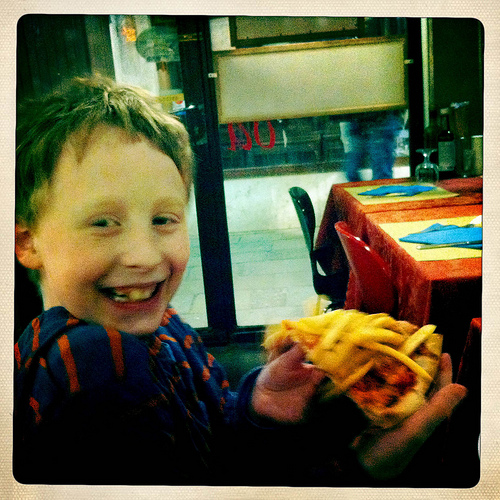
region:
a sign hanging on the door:
[212, 38, 409, 117]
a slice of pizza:
[262, 307, 442, 422]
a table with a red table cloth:
[336, 180, 486, 326]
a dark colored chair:
[286, 186, 344, 307]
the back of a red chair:
[336, 222, 403, 309]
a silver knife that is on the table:
[415, 240, 486, 250]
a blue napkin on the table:
[405, 220, 482, 251]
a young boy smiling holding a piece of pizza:
[18, 112, 465, 487]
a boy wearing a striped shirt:
[16, 111, 246, 466]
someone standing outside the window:
[339, 116, 404, 178]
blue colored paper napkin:
[403, 230, 478, 248]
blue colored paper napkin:
[362, 182, 439, 201]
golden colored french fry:
[365, 340, 433, 381]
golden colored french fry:
[403, 323, 435, 353]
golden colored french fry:
[324, 357, 375, 396]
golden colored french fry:
[323, 312, 355, 352]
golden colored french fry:
[333, 324, 403, 369]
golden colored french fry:
[281, 319, 318, 338]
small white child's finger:
[420, 381, 468, 423]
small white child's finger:
[439, 351, 456, 390]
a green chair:
[284, 185, 349, 308]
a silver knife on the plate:
[418, 238, 480, 245]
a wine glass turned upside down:
[413, 145, 440, 185]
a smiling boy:
[13, 74, 193, 475]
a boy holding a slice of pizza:
[18, 85, 467, 488]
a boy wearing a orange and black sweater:
[16, 80, 263, 491]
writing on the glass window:
[220, 123, 280, 153]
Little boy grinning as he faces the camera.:
[21, 70, 208, 342]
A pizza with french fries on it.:
[242, 289, 458, 434]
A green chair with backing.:
[277, 176, 358, 324]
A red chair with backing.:
[327, 218, 410, 328]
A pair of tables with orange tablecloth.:
[325, 169, 482, 331]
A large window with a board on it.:
[227, 19, 409, 353]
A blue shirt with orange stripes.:
[27, 305, 287, 497]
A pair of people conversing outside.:
[328, 83, 420, 196]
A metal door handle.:
[180, 95, 215, 152]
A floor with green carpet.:
[187, 330, 324, 385]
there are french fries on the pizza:
[248, 287, 450, 442]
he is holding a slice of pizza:
[16, 15, 496, 497]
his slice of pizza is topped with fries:
[1, 10, 468, 495]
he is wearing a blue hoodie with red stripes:
[16, 65, 339, 498]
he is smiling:
[5, 5, 472, 497]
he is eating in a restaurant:
[6, 5, 491, 497]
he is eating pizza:
[3, 5, 490, 499]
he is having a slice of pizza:
[7, 5, 474, 497]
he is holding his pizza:
[10, 28, 473, 475]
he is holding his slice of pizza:
[15, 62, 470, 485]